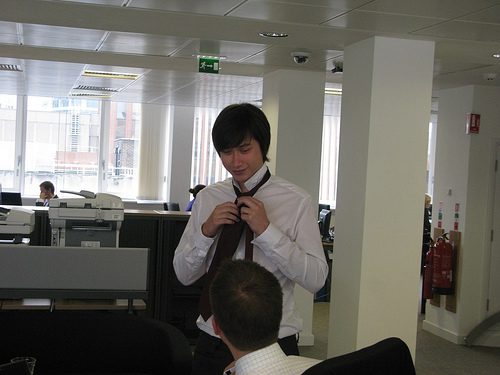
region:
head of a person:
[197, 92, 313, 194]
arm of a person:
[174, 225, 216, 274]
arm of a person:
[230, 193, 303, 270]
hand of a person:
[205, 190, 249, 236]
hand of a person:
[223, 199, 285, 243]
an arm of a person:
[170, 208, 236, 283]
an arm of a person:
[234, 217, 314, 291]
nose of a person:
[230, 155, 250, 169]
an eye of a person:
[239, 140, 253, 161]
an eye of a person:
[223, 142, 242, 156]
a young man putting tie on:
[175, 100, 327, 360]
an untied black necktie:
[197, 167, 270, 318]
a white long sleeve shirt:
[173, 164, 327, 339]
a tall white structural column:
[327, 37, 433, 362]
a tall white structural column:
[261, 71, 319, 347]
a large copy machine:
[43, 186, 125, 247]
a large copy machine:
[1, 203, 35, 243]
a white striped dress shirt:
[233, 343, 330, 373]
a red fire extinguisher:
[432, 232, 451, 294]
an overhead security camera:
[290, 51, 308, 64]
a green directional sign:
[198, 57, 220, 73]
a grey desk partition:
[2, 245, 152, 300]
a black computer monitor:
[318, 207, 331, 237]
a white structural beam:
[166, 105, 193, 211]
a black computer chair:
[304, 335, 419, 372]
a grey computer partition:
[0, 213, 208, 350]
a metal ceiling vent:
[0, 62, 22, 71]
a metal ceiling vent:
[73, 85, 121, 94]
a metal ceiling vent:
[70, 92, 114, 97]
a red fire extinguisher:
[423, 241, 435, 298]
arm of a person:
[164, 221, 224, 292]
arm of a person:
[268, 242, 310, 278]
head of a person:
[198, 246, 294, 354]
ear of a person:
[202, 312, 236, 340]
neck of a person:
[230, 342, 287, 374]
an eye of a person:
[239, 129, 260, 154]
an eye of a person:
[217, 138, 238, 167]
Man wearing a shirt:
[170, 164, 333, 344]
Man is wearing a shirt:
[165, 162, 346, 342]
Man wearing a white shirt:
[164, 162, 331, 342]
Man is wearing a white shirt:
[171, 162, 332, 338]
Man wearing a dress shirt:
[172, 158, 336, 341]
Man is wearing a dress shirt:
[170, 162, 334, 339]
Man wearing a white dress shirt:
[170, 160, 332, 340]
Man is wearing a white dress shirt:
[172, 159, 333, 342]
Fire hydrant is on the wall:
[424, 229, 464, 299]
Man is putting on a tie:
[195, 164, 280, 318]